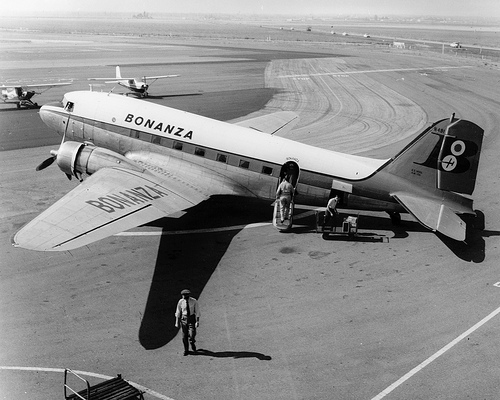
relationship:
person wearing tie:
[162, 273, 214, 361] [185, 299, 192, 322]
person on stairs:
[274, 166, 300, 220] [271, 204, 292, 230]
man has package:
[316, 192, 342, 242] [343, 214, 358, 234]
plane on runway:
[60, 88, 480, 260] [202, 47, 422, 143]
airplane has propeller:
[100, 55, 178, 102] [141, 84, 150, 96]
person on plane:
[274, 166, 300, 220] [60, 88, 480, 260]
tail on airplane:
[388, 95, 489, 259] [60, 88, 480, 260]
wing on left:
[20, 154, 240, 273] [131, 144, 244, 209]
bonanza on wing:
[97, 173, 172, 218] [20, 154, 240, 273]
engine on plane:
[58, 139, 154, 196] [60, 88, 480, 260]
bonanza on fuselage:
[126, 113, 195, 145] [94, 86, 276, 215]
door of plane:
[279, 157, 301, 192] [60, 88, 480, 260]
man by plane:
[316, 192, 393, 258] [60, 88, 480, 260]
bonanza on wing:
[80, 173, 172, 218] [20, 154, 240, 273]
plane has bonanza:
[60, 88, 480, 260] [124, 111, 194, 144]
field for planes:
[65, 2, 446, 115] [22, 62, 327, 219]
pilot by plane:
[163, 287, 208, 326] [60, 88, 480, 260]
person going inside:
[274, 166, 300, 220] [285, 166, 296, 174]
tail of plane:
[388, 95, 489, 259] [60, 88, 480, 260]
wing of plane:
[20, 154, 240, 273] [60, 88, 480, 260]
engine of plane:
[58, 139, 154, 196] [60, 88, 480, 260]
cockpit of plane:
[47, 86, 87, 118] [60, 88, 480, 260]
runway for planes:
[202, 47, 422, 143] [22, 62, 327, 219]